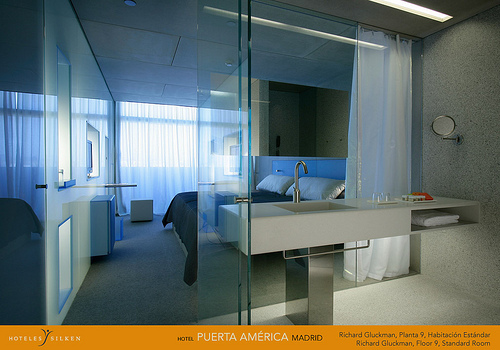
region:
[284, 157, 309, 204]
a chrome bathroom faucet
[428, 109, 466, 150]
a small wall mounted mirror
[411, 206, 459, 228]
white folded towels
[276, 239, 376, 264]
a chrome towel bar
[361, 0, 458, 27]
an overhead fluorescent light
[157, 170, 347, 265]
a king sized bed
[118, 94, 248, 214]
white window curtains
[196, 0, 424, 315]
a large glass dividing wall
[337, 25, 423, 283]
opened white privacy curtains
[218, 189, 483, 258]
a white bathroom vanity countertop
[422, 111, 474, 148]
a small mirror on the wall.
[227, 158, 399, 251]
a white sink across the wall.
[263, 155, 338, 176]
a blue closet .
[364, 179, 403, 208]
plastic cups on the shelf.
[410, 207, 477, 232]
a white towel in the shelf.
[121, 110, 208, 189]
a white shade.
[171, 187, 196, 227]
a black quilt blanket.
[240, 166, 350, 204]
two white pillows on a bed.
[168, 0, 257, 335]
a open glass door.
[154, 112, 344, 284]
a nicely made bed.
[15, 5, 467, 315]
a very modern hotel room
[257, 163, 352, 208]
two large pillows on a bed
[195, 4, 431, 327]
a glass wall between the bedroom and bathroom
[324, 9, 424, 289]
a white curtain between the bedroom and bathroom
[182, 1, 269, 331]
a glass door propped open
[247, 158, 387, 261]
a modern square sink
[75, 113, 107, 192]
television in a built-in shelf in the wall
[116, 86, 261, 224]
window with closed sheer curtain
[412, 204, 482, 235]
neatly folded white towel in bathroom shelf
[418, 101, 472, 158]
wall mounted makeup mirror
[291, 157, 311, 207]
A silver faucet on a sink.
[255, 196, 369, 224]
A white sink area.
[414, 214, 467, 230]
A white towel.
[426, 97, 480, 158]
A small round mirror attached to the wall.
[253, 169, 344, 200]
Two white pillows.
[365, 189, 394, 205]
Clear cups.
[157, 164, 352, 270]
A bed.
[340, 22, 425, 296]
A white curtain.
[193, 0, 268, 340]
A glass see through door.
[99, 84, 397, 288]
A bedroom area.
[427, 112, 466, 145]
a wall mounted makeup mirror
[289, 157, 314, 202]
a long silver faucet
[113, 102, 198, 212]
long white curtains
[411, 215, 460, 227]
a white bath towel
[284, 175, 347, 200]
a long bed pillow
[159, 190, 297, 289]
a black comforter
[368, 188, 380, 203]
a clear plastic cup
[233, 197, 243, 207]
a silver door handle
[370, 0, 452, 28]
part of a ceiling light